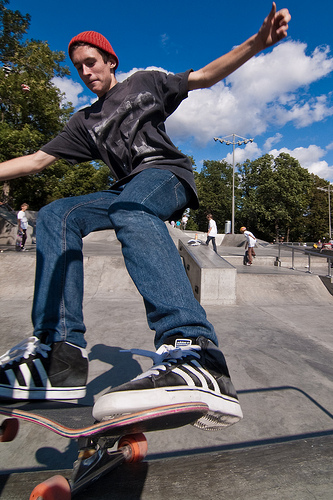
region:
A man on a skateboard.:
[0, 2, 291, 499]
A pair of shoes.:
[1, 336, 242, 432]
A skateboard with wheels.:
[0, 396, 210, 498]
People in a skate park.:
[0, 210, 331, 497]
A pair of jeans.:
[30, 167, 219, 345]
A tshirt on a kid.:
[39, 67, 201, 222]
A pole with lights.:
[212, 133, 253, 233]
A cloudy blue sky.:
[1, 0, 332, 218]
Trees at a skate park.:
[2, 0, 331, 244]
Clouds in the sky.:
[3, 31, 331, 211]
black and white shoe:
[78, 354, 253, 432]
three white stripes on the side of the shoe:
[3, 358, 54, 386]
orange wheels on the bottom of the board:
[22, 418, 163, 498]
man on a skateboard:
[0, 0, 297, 499]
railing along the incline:
[270, 240, 331, 282]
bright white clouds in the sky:
[0, 0, 332, 195]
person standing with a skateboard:
[15, 200, 38, 252]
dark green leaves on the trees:
[178, 151, 330, 242]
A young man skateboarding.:
[6, 5, 295, 493]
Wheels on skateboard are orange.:
[25, 434, 161, 497]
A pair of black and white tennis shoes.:
[1, 330, 240, 421]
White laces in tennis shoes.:
[0, 333, 213, 379]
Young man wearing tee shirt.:
[44, 27, 197, 179]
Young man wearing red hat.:
[61, 26, 118, 95]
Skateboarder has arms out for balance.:
[3, 6, 289, 199]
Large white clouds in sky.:
[41, 28, 326, 183]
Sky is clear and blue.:
[14, 2, 322, 159]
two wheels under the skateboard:
[29, 434, 148, 498]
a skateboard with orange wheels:
[0, 400, 210, 498]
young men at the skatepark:
[0, 0, 290, 429]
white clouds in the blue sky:
[190, 91, 331, 130]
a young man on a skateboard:
[0, 1, 292, 499]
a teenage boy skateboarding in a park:
[0, 1, 291, 499]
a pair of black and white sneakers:
[0, 333, 242, 430]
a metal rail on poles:
[276, 244, 331, 276]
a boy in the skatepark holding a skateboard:
[11, 202, 31, 251]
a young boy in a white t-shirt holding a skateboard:
[13, 202, 29, 253]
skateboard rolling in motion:
[0, 400, 206, 496]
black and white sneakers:
[91, 336, 239, 426]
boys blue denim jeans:
[32, 168, 218, 343]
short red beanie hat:
[68, 30, 119, 63]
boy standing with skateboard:
[14, 203, 29, 251]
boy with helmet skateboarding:
[238, 226, 258, 266]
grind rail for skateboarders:
[279, 242, 332, 280]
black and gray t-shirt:
[40, 68, 193, 184]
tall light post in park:
[213, 133, 254, 231]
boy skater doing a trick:
[3, 1, 294, 498]